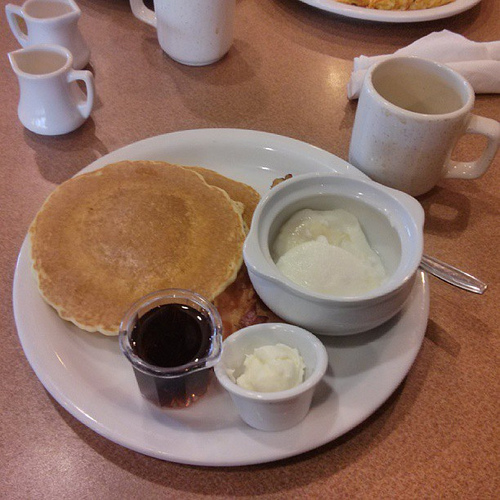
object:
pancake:
[27, 160, 249, 338]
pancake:
[177, 166, 269, 341]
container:
[210, 322, 326, 431]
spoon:
[420, 253, 488, 296]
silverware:
[417, 255, 486, 294]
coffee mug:
[344, 53, 499, 212]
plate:
[283, 0, 477, 22]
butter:
[227, 343, 307, 393]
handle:
[421, 258, 488, 297]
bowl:
[237, 169, 430, 338]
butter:
[271, 206, 395, 300]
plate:
[9, 127, 429, 467]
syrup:
[132, 309, 212, 366]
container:
[118, 286, 225, 410]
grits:
[266, 207, 390, 279]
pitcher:
[2, 1, 91, 72]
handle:
[442, 111, 498, 181]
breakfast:
[26, 156, 250, 339]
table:
[0, 1, 499, 499]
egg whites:
[270, 205, 389, 299]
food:
[29, 156, 251, 340]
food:
[275, 237, 381, 295]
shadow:
[44, 316, 459, 497]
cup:
[6, 42, 98, 136]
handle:
[63, 70, 96, 121]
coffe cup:
[124, 0, 235, 67]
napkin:
[345, 29, 499, 104]